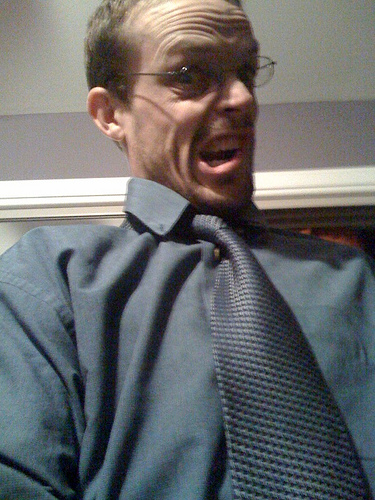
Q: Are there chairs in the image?
A: No, there are no chairs.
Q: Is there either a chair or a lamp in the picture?
A: No, there are no chairs or lamps.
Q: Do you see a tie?
A: Yes, there is a tie.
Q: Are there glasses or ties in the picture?
A: Yes, there is a tie.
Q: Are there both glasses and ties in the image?
A: Yes, there are both a tie and glasses.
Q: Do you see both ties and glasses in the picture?
A: Yes, there are both a tie and glasses.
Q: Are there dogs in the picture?
A: No, there are no dogs.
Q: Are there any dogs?
A: No, there are no dogs.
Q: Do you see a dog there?
A: No, there are no dogs.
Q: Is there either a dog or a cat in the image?
A: No, there are no dogs or cats.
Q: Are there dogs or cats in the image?
A: No, there are no dogs or cats.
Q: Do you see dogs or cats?
A: No, there are no dogs or cats.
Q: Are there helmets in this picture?
A: No, there are no helmets.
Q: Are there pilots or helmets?
A: No, there are no helmets or pilots.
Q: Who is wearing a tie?
A: The man is wearing a tie.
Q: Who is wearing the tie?
A: The man is wearing a tie.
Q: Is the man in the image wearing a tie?
A: Yes, the man is wearing a tie.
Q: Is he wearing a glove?
A: No, the man is wearing a tie.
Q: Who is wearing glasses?
A: The man is wearing glasses.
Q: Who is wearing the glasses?
A: The man is wearing glasses.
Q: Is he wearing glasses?
A: Yes, the man is wearing glasses.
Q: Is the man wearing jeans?
A: No, the man is wearing glasses.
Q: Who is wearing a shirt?
A: The man is wearing a shirt.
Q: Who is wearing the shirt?
A: The man is wearing a shirt.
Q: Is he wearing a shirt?
A: Yes, the man is wearing a shirt.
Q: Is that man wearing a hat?
A: No, the man is wearing a shirt.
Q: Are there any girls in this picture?
A: No, there are no girls.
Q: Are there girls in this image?
A: No, there are no girls.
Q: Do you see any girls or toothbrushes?
A: No, there are no girls or toothbrushes.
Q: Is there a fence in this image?
A: No, there are no fences.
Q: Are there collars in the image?
A: Yes, there is a collar.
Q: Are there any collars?
A: Yes, there is a collar.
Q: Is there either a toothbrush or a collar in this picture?
A: Yes, there is a collar.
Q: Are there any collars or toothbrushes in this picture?
A: Yes, there is a collar.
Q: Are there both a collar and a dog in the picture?
A: No, there is a collar but no dogs.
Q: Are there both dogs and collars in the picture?
A: No, there is a collar but no dogs.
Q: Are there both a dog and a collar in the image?
A: No, there is a collar but no dogs.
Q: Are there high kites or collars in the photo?
A: Yes, there is a high collar.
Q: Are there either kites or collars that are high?
A: Yes, the collar is high.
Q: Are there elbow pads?
A: No, there are no elbow pads.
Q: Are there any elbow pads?
A: No, there are no elbow pads.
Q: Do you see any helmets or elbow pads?
A: No, there are no elbow pads or helmets.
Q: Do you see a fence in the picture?
A: No, there are no fences.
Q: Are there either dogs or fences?
A: No, there are no fences or dogs.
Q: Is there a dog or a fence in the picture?
A: No, there are no fences or dogs.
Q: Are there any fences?
A: No, there are no fences.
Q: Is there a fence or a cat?
A: No, there are no fences or cats.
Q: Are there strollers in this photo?
A: No, there are no strollers.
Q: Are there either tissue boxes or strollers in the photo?
A: No, there are no strollers or tissue boxes.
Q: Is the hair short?
A: Yes, the hair is short.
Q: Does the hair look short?
A: Yes, the hair is short.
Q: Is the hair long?
A: No, the hair is short.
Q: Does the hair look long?
A: No, the hair is short.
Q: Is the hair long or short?
A: The hair is short.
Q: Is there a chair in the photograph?
A: No, there are no chairs.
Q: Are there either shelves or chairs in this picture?
A: No, there are no chairs or shelves.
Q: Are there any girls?
A: No, there are no girls.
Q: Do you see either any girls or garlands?
A: No, there are no girls or garlands.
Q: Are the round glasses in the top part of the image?
A: Yes, the glasses are in the top of the image.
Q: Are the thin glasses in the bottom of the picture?
A: No, the glasses are in the top of the image.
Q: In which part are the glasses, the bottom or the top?
A: The glasses are in the top of the image.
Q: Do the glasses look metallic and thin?
A: Yes, the glasses are metallic and thin.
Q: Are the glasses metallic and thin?
A: Yes, the glasses are metallic and thin.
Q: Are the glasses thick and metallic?
A: No, the glasses are metallic but thin.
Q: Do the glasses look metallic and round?
A: Yes, the glasses are metallic and round.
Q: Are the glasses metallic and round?
A: Yes, the glasses are metallic and round.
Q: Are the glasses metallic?
A: Yes, the glasses are metallic.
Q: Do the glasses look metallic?
A: Yes, the glasses are metallic.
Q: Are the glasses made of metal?
A: Yes, the glasses are made of metal.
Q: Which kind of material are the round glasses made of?
A: The glasses are made of metal.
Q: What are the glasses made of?
A: The glasses are made of metal.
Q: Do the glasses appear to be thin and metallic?
A: Yes, the glasses are thin and metallic.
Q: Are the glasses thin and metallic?
A: Yes, the glasses are thin and metallic.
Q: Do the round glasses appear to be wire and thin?
A: No, the glasses are thin but metallic.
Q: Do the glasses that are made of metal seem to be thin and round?
A: Yes, the glasses are thin and round.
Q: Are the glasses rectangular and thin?
A: No, the glasses are thin but round.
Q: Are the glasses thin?
A: Yes, the glasses are thin.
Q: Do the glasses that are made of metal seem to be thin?
A: Yes, the glasses are thin.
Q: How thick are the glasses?
A: The glasses are thin.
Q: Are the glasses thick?
A: No, the glasses are thin.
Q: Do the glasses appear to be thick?
A: No, the glasses are thin.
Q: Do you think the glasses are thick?
A: No, the glasses are thin.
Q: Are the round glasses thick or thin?
A: The glasses are thin.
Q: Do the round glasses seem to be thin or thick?
A: The glasses are thin.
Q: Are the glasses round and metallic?
A: Yes, the glasses are round and metallic.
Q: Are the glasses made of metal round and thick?
A: No, the glasses are round but thin.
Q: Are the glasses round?
A: Yes, the glasses are round.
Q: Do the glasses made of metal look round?
A: Yes, the glasses are round.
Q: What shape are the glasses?
A: The glasses are round.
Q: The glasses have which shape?
A: The glasses are round.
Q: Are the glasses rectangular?
A: No, the glasses are round.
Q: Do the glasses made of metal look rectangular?
A: No, the glasses are round.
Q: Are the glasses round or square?
A: The glasses are round.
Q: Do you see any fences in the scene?
A: No, there are no fences.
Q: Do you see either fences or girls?
A: No, there are no fences or girls.